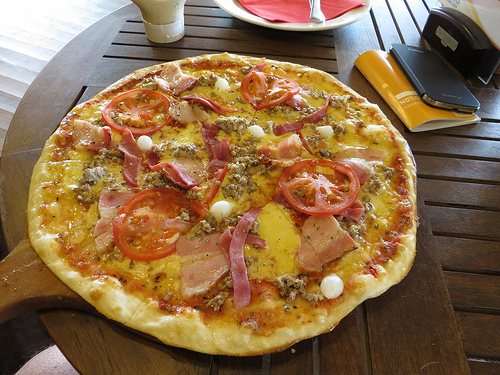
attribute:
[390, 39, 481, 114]
cellphone — black, electronic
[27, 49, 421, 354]
pizza — round, whole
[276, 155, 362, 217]
tomato — sliced, topping, slice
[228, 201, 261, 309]
ham — topping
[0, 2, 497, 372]
table — brown, wood, wooden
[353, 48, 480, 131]
book — yellow, small, planner, paper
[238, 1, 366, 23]
napkin — red, paper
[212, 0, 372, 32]
plate — white, round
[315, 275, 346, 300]
ball — white, cheese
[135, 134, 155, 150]
ball — white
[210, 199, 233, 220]
ball — white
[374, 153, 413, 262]
sauce — tomato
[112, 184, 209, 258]
tomato — sliced, slice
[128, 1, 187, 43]
cup — bottle, condiment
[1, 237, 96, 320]
board — wooden, wood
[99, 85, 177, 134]
tomato — slice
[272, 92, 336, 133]
bacon — topping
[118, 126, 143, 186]
strip — ham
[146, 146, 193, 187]
strip — ham